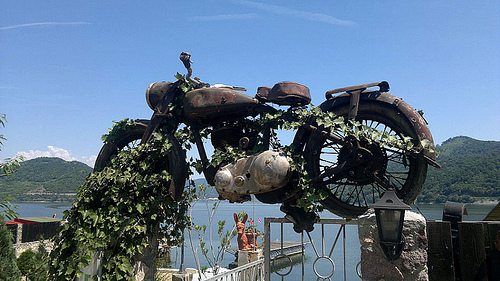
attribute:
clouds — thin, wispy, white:
[308, 1, 390, 62]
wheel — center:
[330, 130, 389, 186]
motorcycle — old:
[97, 48, 425, 212]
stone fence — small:
[360, 208, 428, 275]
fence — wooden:
[427, 218, 497, 280]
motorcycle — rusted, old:
[53, 66, 375, 216]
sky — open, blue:
[3, 0, 498, 156]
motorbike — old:
[93, 50, 439, 231]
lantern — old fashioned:
[371, 183, 411, 260]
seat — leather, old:
[247, 78, 313, 112]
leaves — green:
[58, 144, 172, 279]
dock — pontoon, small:
[226, 236, 308, 274]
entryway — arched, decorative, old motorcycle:
[56, 50, 437, 280]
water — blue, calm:
[0, 195, 498, 278]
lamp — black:
[376, 187, 408, 257]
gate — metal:
[257, 214, 369, 280]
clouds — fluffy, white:
[8, 144, 97, 164]